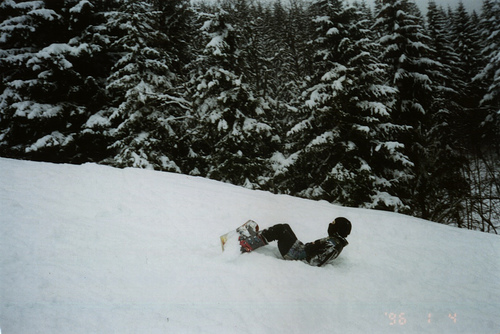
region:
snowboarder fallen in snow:
[232, 200, 315, 265]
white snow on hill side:
[37, 195, 77, 225]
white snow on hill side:
[60, 223, 115, 267]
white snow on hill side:
[390, 289, 420, 308]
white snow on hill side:
[404, 248, 431, 265]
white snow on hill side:
[317, 289, 341, 310]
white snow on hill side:
[198, 260, 244, 305]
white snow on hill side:
[77, 283, 137, 323]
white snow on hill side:
[123, 221, 160, 243]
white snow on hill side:
[61, 217, 107, 250]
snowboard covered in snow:
[219, 219, 259, 250]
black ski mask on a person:
[326, 215, 353, 237]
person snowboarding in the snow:
[220, 215, 353, 266]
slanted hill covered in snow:
[0, 155, 497, 332]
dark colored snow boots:
[238, 231, 269, 253]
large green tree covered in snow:
[278, 0, 414, 212]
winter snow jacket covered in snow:
[284, 232, 349, 267]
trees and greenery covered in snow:
[1, 0, 497, 231]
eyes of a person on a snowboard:
[330, 218, 337, 225]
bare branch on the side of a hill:
[477, 210, 496, 232]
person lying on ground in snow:
[212, 187, 365, 272]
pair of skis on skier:
[208, 209, 265, 265]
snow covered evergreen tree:
[272, 4, 417, 220]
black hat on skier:
[318, 210, 370, 241]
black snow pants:
[263, 217, 298, 256]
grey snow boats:
[230, 219, 271, 254]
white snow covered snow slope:
[3, 147, 492, 331]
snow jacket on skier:
[278, 231, 350, 267]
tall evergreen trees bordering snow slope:
[3, 2, 498, 227]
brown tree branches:
[466, 167, 498, 234]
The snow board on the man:
[215, 211, 259, 252]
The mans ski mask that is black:
[325, 215, 353, 240]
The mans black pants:
[255, 221, 287, 252]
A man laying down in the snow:
[213, 216, 391, 277]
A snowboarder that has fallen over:
[209, 191, 370, 272]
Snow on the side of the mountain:
[0, 171, 497, 326]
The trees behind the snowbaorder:
[2, 5, 497, 219]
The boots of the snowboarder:
[237, 231, 271, 259]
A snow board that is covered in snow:
[222, 216, 254, 263]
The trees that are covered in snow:
[20, 6, 498, 238]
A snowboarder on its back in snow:
[211, 206, 356, 280]